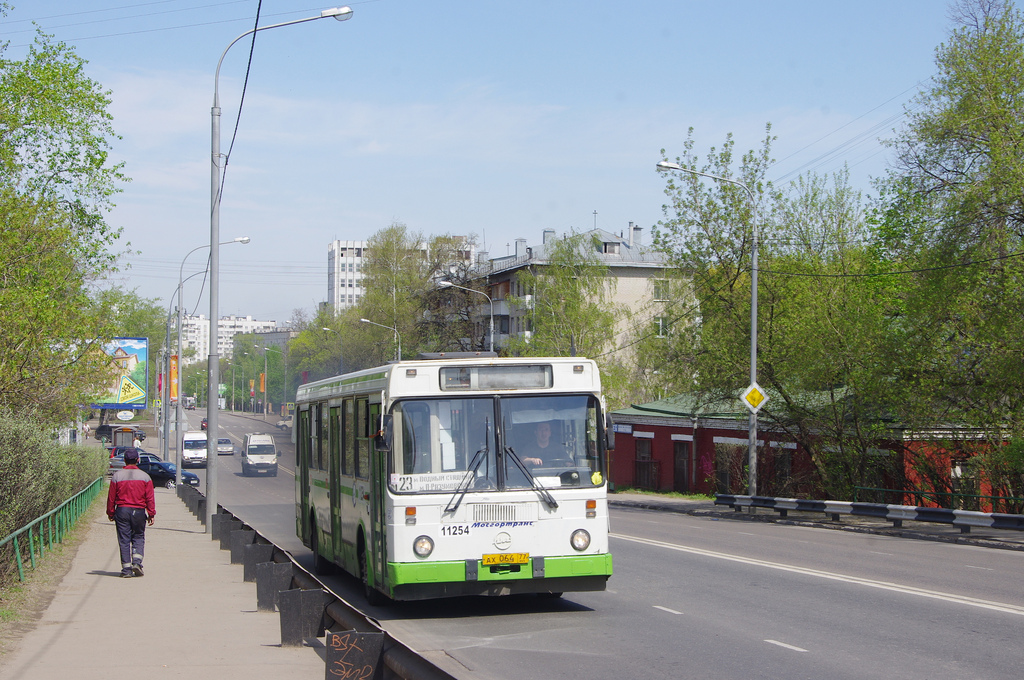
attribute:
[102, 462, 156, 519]
jacket — red, grey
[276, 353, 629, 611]
bus — white, green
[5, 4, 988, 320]
sky — blue, bright, clear, light, sunny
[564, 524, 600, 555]
headlight — black, white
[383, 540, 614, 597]
bumper — green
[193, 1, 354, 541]
street light — grey, tall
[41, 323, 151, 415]
billboard — large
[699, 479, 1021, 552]
road barrier — white, black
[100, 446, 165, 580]
man — walking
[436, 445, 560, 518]
windshield wipers — black, skinny, tall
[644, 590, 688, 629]
line — white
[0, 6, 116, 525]
tree — green